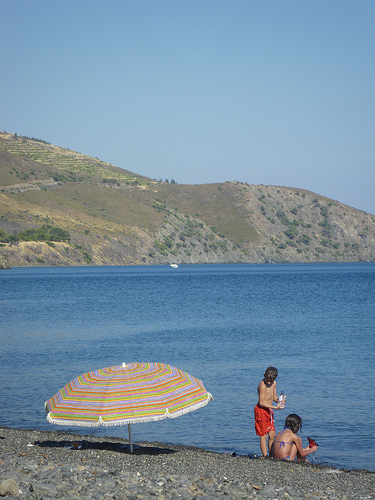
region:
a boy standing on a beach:
[248, 336, 281, 474]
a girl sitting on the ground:
[270, 415, 317, 468]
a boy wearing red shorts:
[257, 400, 282, 445]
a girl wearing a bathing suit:
[263, 404, 309, 471]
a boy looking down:
[258, 351, 292, 401]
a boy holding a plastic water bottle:
[270, 385, 289, 408]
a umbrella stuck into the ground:
[66, 317, 209, 472]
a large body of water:
[39, 246, 360, 349]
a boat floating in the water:
[150, 249, 185, 289]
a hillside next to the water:
[113, 173, 350, 305]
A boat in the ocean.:
[163, 252, 184, 277]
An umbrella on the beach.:
[38, 348, 227, 468]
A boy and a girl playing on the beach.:
[238, 361, 343, 469]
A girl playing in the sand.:
[270, 412, 319, 471]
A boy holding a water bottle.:
[247, 361, 289, 456]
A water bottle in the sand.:
[57, 436, 89, 457]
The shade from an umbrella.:
[39, 434, 184, 464]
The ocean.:
[43, 335, 240, 476]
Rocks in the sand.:
[38, 481, 132, 497]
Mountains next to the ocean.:
[33, 164, 348, 273]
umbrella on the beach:
[48, 345, 211, 434]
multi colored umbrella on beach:
[84, 358, 172, 420]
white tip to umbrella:
[118, 358, 129, 368]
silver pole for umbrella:
[122, 421, 133, 454]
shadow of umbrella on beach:
[37, 423, 173, 462]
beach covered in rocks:
[72, 452, 223, 496]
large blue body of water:
[11, 255, 347, 361]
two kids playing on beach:
[242, 356, 312, 477]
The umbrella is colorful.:
[26, 332, 231, 475]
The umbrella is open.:
[42, 329, 234, 474]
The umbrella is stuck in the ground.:
[39, 335, 247, 497]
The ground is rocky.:
[0, 423, 373, 498]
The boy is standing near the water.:
[244, 345, 291, 461]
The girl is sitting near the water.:
[271, 398, 346, 478]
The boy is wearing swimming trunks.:
[242, 341, 290, 465]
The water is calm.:
[1, 258, 374, 478]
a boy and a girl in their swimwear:
[250, 363, 321, 464]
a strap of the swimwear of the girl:
[271, 437, 294, 445]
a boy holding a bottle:
[250, 362, 288, 460]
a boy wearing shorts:
[252, 362, 287, 462]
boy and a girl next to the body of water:
[249, 363, 320, 466]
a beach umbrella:
[41, 358, 215, 458]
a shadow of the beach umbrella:
[33, 436, 179, 458]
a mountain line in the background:
[1, 125, 373, 262]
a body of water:
[0, 271, 374, 344]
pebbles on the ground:
[0, 464, 273, 497]